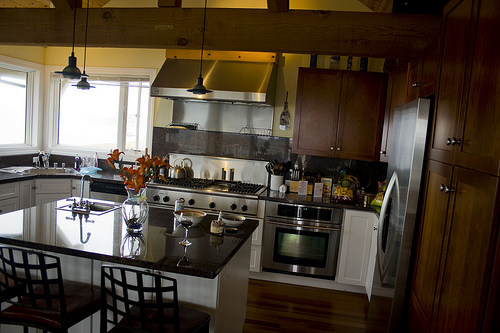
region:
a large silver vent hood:
[152, 46, 277, 111]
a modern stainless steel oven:
[262, 197, 340, 278]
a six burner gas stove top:
[167, 164, 262, 202]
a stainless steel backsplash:
[155, 151, 269, 188]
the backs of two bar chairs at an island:
[5, 243, 188, 329]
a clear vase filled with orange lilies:
[109, 146, 164, 238]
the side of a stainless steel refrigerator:
[364, 101, 435, 330]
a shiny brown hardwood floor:
[256, 285, 323, 324]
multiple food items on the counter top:
[289, 154, 391, 204]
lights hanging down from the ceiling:
[50, 50, 209, 102]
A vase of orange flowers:
[108, 152, 163, 235]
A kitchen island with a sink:
[3, 186, 244, 331]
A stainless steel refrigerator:
[361, 97, 431, 330]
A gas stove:
[141, 171, 257, 217]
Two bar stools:
[2, 248, 222, 330]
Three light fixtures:
[49, 34, 221, 104]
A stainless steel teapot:
[162, 157, 194, 183]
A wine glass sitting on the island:
[178, 209, 198, 256]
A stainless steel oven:
[261, 200, 349, 287]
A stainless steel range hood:
[145, 54, 291, 115]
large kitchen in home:
[42, 21, 382, 329]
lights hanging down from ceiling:
[67, 23, 226, 111]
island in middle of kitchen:
[28, 180, 236, 294]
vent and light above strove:
[82, 52, 287, 120]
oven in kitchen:
[221, 195, 361, 282]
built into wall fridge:
[301, 105, 452, 332]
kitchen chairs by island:
[3, 257, 180, 327]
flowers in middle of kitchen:
[123, 141, 158, 226]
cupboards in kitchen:
[303, 68, 388, 166]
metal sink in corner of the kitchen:
[21, 148, 76, 196]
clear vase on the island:
[118, 181, 155, 237]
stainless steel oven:
[258, 193, 343, 283]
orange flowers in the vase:
[105, 145, 167, 197]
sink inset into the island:
[63, 171, 116, 220]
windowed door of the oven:
[269, 225, 330, 271]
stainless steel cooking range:
[143, 167, 262, 221]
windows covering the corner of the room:
[1, 55, 158, 167]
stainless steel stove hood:
[149, 43, 281, 113]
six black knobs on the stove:
[146, 190, 256, 215]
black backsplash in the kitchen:
[149, 123, 391, 200]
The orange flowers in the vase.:
[107, 144, 168, 200]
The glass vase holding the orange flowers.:
[122, 182, 149, 234]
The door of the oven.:
[265, 215, 336, 271]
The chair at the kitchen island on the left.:
[0, 240, 92, 330]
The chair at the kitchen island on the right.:
[96, 250, 201, 330]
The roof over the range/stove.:
[150, 50, 270, 105]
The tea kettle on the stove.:
[166, 151, 181, 172]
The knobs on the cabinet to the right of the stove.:
[325, 141, 343, 151]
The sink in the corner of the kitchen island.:
[47, 162, 118, 227]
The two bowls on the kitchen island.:
[170, 206, 245, 226]